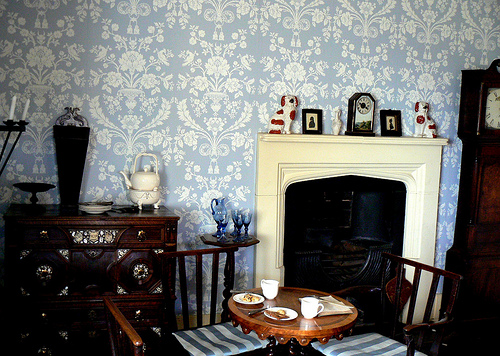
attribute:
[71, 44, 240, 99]
blue wallpaper — white design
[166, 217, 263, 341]
table — small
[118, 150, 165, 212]
kettle — white, antique, crisp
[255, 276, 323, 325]
cups — white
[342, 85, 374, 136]
clock — small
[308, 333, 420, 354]
stripes — blue, white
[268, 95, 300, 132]
dog — white, red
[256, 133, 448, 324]
fireplace — white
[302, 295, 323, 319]
cup — white, coffee cup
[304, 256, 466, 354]
bars — shiny, narrow, wooden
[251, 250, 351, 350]
paper — pieces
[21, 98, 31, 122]
candle — long, white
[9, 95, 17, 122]
candle — long, white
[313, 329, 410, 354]
seat — striped, chair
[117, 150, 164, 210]
teapot — white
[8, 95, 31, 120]
candles — white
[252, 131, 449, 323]
mantel — white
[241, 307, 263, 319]
cutlery — silver, metallic, piece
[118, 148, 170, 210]
teapot — white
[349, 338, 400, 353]
seat — stripped white, stripped blue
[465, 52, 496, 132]
clock — grandfather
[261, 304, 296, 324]
saucer — white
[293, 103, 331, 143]
photo — silhouette, person